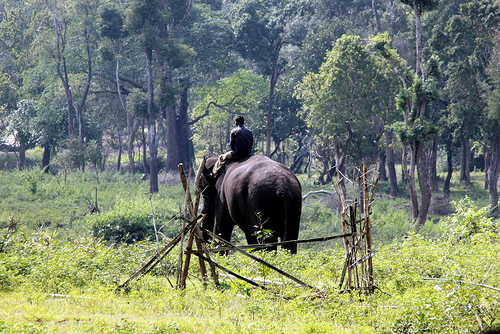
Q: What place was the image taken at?
A: It was taken at the forest.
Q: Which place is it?
A: It is a forest.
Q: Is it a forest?
A: Yes, it is a forest.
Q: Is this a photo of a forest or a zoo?
A: It is showing a forest.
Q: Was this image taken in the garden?
A: No, the picture was taken in the forest.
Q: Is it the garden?
A: No, it is the forest.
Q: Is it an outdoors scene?
A: Yes, it is outdoors.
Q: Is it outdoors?
A: Yes, it is outdoors.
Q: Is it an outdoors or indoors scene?
A: It is outdoors.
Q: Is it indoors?
A: No, it is outdoors.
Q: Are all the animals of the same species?
A: Yes, all the animals are elephants.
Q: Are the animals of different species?
A: No, all the animals are elephants.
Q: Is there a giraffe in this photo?
A: No, there are no giraffes.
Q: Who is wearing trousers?
A: The man is wearing trousers.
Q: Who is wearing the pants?
A: The man is wearing trousers.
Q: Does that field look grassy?
A: Yes, the field is grassy.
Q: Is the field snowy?
A: No, the field is grassy.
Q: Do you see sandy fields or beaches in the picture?
A: No, there is a field but it is grassy.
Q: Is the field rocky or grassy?
A: The field is grassy.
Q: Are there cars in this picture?
A: No, there are no cars.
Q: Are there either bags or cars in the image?
A: No, there are no cars or bags.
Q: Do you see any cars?
A: No, there are no cars.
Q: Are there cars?
A: No, there are no cars.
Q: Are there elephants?
A: Yes, there is an elephant.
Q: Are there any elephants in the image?
A: Yes, there is an elephant.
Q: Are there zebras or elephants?
A: Yes, there is an elephant.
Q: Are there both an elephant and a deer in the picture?
A: No, there is an elephant but no deer.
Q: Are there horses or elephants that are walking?
A: Yes, the elephant is walking.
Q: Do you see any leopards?
A: No, there are no leopards.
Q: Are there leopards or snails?
A: No, there are no leopards or snails.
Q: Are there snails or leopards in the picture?
A: No, there are no leopards or snails.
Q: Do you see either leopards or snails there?
A: No, there are no leopards or snails.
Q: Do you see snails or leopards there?
A: No, there are no leopards or snails.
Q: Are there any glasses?
A: No, there are no glasses.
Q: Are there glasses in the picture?
A: No, there are no glasses.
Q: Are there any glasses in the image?
A: No, there are no glasses.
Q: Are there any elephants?
A: Yes, there is an elephant.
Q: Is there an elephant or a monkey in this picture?
A: Yes, there is an elephant.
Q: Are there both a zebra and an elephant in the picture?
A: No, there is an elephant but no zebras.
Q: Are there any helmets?
A: No, there are no helmets.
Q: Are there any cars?
A: No, there are no cars.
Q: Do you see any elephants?
A: Yes, there is an elephant.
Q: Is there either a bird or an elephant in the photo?
A: Yes, there is an elephant.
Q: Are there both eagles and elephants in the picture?
A: No, there is an elephant but no eagles.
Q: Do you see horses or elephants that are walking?
A: Yes, the elephant is walking.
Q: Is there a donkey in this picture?
A: No, there are no donkeys.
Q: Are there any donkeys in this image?
A: No, there are no donkeys.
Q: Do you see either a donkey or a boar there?
A: No, there are no donkeys or boars.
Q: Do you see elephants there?
A: Yes, there is an elephant.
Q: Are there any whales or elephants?
A: Yes, there is an elephant.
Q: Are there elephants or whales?
A: Yes, there is an elephant.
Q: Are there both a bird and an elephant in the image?
A: No, there is an elephant but no birds.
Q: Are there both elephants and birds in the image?
A: No, there is an elephant but no birds.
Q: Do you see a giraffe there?
A: No, there are no giraffes.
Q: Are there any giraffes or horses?
A: No, there are no giraffes or horses.